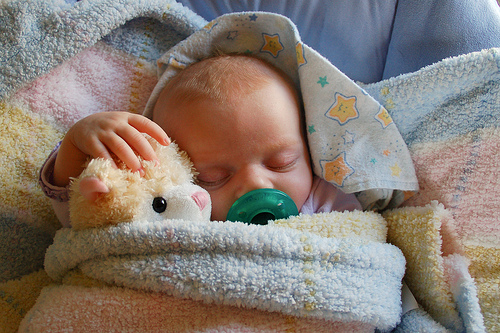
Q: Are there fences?
A: No, there are no fences.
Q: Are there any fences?
A: No, there are no fences.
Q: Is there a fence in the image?
A: No, there are no fences.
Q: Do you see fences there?
A: No, there are no fences.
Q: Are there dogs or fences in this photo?
A: No, there are no fences or dogs.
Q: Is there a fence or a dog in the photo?
A: No, there are no fences or dogs.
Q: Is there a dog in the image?
A: No, there are no dogs.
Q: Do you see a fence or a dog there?
A: No, there are no dogs or fences.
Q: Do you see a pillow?
A: Yes, there is a pillow.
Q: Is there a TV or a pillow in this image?
A: Yes, there is a pillow.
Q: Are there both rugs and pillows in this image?
A: No, there is a pillow but no rugs.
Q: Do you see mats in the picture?
A: No, there are no mats.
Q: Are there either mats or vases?
A: No, there are no mats or vases.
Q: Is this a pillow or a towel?
A: This is a pillow.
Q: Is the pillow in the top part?
A: Yes, the pillow is in the top of the image.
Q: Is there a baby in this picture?
A: Yes, there is a baby.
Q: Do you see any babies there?
A: Yes, there is a baby.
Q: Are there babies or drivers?
A: Yes, there is a baby.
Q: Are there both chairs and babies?
A: No, there is a baby but no chairs.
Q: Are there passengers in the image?
A: No, there are no passengers.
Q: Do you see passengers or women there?
A: No, there are no passengers or women.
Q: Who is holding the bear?
A: The baby is holding the bear.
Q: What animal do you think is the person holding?
A: The baby is holding the bear.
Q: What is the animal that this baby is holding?
A: The animal is a bear.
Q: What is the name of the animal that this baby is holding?
A: The animal is a bear.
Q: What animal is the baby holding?
A: The baby is holding the bear.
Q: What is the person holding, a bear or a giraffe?
A: The baby is holding a bear.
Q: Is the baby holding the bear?
A: Yes, the baby is holding the bear.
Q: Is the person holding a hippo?
A: No, the baby is holding the bear.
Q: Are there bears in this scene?
A: Yes, there is a bear.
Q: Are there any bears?
A: Yes, there is a bear.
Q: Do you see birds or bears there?
A: Yes, there is a bear.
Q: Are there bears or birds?
A: Yes, there is a bear.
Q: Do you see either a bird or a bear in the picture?
A: Yes, there is a bear.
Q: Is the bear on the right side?
A: No, the bear is on the left of the image.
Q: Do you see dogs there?
A: No, there are no dogs.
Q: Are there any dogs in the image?
A: No, there are no dogs.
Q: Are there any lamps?
A: No, there are no lamps.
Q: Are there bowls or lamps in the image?
A: No, there are no lamps or bowls.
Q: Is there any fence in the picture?
A: No, there are no fences.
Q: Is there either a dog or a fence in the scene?
A: No, there are no fences or dogs.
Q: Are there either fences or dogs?
A: No, there are no fences or dogs.